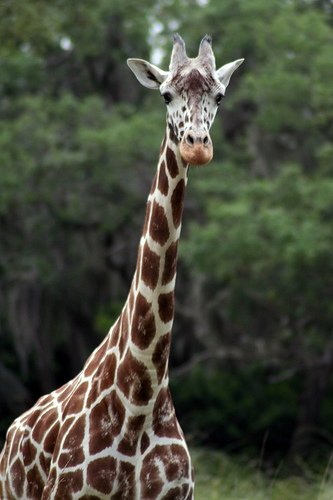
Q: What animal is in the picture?
A: Giraffe.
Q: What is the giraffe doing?
A: Standing.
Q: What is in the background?
A: Trees.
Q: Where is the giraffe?
A: In the wild.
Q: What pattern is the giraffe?
A: Spotted.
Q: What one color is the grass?
A: Green.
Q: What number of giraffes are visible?
A: One.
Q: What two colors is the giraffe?
A: Brown and white.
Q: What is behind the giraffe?
A: Trees.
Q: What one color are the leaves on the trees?
A: Green.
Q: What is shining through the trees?
A: Sunlight.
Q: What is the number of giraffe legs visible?
A: Zero.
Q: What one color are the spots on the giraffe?
A: Brown.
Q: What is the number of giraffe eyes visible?
A: Two.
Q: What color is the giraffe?
A: Brown and white.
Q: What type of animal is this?
A: Giraffe.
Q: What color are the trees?
A: Green.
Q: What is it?
A: Giraffe.